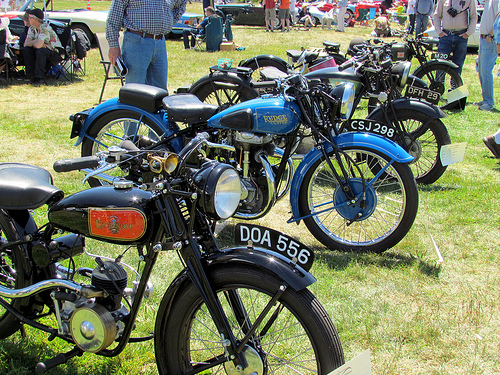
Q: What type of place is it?
A: It is a meadow.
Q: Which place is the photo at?
A: It is at the meadow.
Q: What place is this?
A: It is a meadow.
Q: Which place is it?
A: It is a meadow.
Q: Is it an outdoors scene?
A: Yes, it is outdoors.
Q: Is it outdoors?
A: Yes, it is outdoors.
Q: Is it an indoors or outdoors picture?
A: It is outdoors.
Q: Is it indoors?
A: No, it is outdoors.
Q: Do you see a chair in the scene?
A: Yes, there is a chair.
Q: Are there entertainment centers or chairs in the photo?
A: Yes, there is a chair.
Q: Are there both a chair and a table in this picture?
A: No, there is a chair but no tables.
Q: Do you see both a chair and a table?
A: No, there is a chair but no tables.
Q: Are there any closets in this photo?
A: No, there are no closets.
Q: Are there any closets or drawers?
A: No, there are no closets or drawers.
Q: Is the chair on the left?
A: Yes, the chair is on the left of the image.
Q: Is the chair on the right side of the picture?
A: No, the chair is on the left of the image.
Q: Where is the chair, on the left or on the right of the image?
A: The chair is on the left of the image.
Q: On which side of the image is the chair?
A: The chair is on the left of the image.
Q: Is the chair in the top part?
A: Yes, the chair is in the top of the image.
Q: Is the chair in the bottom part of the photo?
A: No, the chair is in the top of the image.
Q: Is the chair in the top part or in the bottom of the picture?
A: The chair is in the top of the image.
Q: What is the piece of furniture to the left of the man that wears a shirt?
A: The piece of furniture is a chair.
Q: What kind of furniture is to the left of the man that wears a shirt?
A: The piece of furniture is a chair.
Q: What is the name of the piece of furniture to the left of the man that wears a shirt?
A: The piece of furniture is a chair.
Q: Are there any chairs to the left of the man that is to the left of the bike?
A: Yes, there is a chair to the left of the man.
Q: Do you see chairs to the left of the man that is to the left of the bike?
A: Yes, there is a chair to the left of the man.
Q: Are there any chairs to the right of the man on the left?
A: No, the chair is to the left of the man.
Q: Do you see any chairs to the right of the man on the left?
A: No, the chair is to the left of the man.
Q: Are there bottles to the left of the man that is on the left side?
A: No, there is a chair to the left of the man.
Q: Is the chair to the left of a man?
A: Yes, the chair is to the left of a man.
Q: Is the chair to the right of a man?
A: No, the chair is to the left of a man.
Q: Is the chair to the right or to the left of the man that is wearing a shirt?
A: The chair is to the left of the man.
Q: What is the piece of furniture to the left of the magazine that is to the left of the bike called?
A: The piece of furniture is a chair.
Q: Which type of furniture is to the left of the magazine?
A: The piece of furniture is a chair.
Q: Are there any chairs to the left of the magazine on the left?
A: Yes, there is a chair to the left of the magazine.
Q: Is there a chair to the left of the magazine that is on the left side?
A: Yes, there is a chair to the left of the magazine.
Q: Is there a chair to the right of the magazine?
A: No, the chair is to the left of the magazine.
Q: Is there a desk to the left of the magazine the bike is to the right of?
A: No, there is a chair to the left of the magazine.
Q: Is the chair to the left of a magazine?
A: Yes, the chair is to the left of a magazine.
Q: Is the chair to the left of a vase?
A: No, the chair is to the left of a magazine.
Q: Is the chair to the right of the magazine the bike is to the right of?
A: No, the chair is to the left of the magazine.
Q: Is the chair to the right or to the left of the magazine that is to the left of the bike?
A: The chair is to the left of the magazine.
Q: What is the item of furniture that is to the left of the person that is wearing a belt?
A: The piece of furniture is a chair.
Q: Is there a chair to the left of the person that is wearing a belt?
A: Yes, there is a chair to the left of the person.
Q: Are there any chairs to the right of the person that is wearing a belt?
A: No, the chair is to the left of the person.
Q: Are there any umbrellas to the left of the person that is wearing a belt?
A: No, there is a chair to the left of the person.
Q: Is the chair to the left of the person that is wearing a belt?
A: Yes, the chair is to the left of the person.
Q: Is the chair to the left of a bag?
A: No, the chair is to the left of the person.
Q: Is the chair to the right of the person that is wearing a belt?
A: No, the chair is to the left of the person.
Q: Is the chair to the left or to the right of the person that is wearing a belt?
A: The chair is to the left of the person.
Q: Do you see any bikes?
A: Yes, there is a bike.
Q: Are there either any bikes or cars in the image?
A: Yes, there is a bike.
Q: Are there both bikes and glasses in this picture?
A: No, there is a bike but no glasses.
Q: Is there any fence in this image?
A: No, there are no fences.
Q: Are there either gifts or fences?
A: No, there are no fences or gifts.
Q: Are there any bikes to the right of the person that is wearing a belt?
A: Yes, there is a bike to the right of the person.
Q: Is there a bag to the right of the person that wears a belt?
A: No, there is a bike to the right of the person.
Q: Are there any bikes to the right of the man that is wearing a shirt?
A: Yes, there is a bike to the right of the man.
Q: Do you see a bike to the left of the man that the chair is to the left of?
A: No, the bike is to the right of the man.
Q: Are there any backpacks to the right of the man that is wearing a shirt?
A: No, there is a bike to the right of the man.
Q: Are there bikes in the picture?
A: Yes, there is a bike.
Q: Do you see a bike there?
A: Yes, there is a bike.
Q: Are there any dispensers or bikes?
A: Yes, there is a bike.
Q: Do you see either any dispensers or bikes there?
A: Yes, there is a bike.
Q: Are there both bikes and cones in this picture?
A: No, there is a bike but no cones.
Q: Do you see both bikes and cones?
A: No, there is a bike but no cones.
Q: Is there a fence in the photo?
A: No, there are no fences.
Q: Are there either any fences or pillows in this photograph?
A: No, there are no fences or pillows.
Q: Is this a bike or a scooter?
A: This is a bike.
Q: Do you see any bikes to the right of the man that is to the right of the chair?
A: Yes, there is a bike to the right of the man.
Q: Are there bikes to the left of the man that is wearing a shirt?
A: No, the bike is to the right of the man.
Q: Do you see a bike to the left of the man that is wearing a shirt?
A: No, the bike is to the right of the man.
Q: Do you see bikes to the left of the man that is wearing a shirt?
A: No, the bike is to the right of the man.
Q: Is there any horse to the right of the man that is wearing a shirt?
A: No, there is a bike to the right of the man.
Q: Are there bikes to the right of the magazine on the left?
A: Yes, there is a bike to the right of the magazine.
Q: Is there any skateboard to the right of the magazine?
A: No, there is a bike to the right of the magazine.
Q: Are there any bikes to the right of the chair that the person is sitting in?
A: Yes, there is a bike to the right of the chair.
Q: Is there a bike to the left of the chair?
A: No, the bike is to the right of the chair.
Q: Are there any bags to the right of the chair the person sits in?
A: No, there is a bike to the right of the chair.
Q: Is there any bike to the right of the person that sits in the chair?
A: Yes, there is a bike to the right of the person.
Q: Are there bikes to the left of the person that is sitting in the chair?
A: No, the bike is to the right of the person.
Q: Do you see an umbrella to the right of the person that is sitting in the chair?
A: No, there is a bike to the right of the person.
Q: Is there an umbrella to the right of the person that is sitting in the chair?
A: No, there is a bike to the right of the person.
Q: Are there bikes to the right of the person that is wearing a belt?
A: Yes, there is a bike to the right of the person.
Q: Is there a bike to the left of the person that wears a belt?
A: No, the bike is to the right of the person.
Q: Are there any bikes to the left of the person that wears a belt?
A: No, the bike is to the right of the person.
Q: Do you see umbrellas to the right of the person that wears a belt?
A: No, there is a bike to the right of the person.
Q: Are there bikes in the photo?
A: Yes, there is a bike.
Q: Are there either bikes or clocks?
A: Yes, there is a bike.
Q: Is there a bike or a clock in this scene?
A: Yes, there is a bike.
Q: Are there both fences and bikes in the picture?
A: No, there is a bike but no fences.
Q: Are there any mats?
A: No, there are no mats.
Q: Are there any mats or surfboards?
A: No, there are no mats or surfboards.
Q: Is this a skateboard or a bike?
A: This is a bike.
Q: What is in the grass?
A: The bike is in the grass.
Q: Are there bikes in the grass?
A: Yes, there is a bike in the grass.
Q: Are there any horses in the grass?
A: No, there is a bike in the grass.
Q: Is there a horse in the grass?
A: No, there is a bike in the grass.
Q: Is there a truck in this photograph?
A: No, there are no trucks.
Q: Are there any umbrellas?
A: No, there are no umbrellas.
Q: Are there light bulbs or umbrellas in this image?
A: No, there are no umbrellas or light bulbs.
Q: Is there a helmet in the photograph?
A: No, there are no helmets.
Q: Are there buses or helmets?
A: No, there are no helmets or buses.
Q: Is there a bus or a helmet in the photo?
A: No, there are no helmets or buses.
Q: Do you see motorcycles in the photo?
A: Yes, there is a motorcycle.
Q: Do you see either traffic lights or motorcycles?
A: Yes, there is a motorcycle.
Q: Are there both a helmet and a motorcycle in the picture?
A: No, there is a motorcycle but no helmets.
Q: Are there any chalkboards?
A: No, there are no chalkboards.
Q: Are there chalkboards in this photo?
A: No, there are no chalkboards.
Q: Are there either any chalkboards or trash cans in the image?
A: No, there are no chalkboards or trash cans.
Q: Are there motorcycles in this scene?
A: Yes, there is a motorcycle.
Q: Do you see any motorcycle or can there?
A: Yes, there is a motorcycle.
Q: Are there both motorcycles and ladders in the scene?
A: No, there is a motorcycle but no ladders.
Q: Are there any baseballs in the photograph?
A: No, there are no baseballs.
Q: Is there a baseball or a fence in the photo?
A: No, there are no baseballs or fences.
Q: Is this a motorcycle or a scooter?
A: This is a motorcycle.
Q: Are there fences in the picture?
A: No, there are no fences.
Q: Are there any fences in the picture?
A: No, there are no fences.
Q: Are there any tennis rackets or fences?
A: No, there are no fences or tennis rackets.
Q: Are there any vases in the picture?
A: No, there are no vases.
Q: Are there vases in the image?
A: No, there are no vases.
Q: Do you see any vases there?
A: No, there are no vases.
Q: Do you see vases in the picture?
A: No, there are no vases.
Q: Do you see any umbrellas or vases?
A: No, there are no vases or umbrellas.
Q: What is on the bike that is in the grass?
A: The seat is on the bike.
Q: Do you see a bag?
A: No, there are no bags.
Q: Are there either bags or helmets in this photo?
A: No, there are no bags or helmets.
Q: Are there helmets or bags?
A: No, there are no bags or helmets.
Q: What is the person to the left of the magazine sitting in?
A: The person is sitting in the chair.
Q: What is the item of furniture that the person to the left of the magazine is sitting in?
A: The piece of furniture is a chair.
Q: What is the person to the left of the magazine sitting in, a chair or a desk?
A: The person is sitting in a chair.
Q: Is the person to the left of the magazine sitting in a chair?
A: Yes, the person is sitting in a chair.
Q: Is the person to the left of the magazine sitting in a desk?
A: No, the person is sitting in a chair.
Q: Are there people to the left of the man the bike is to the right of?
A: Yes, there is a person to the left of the man.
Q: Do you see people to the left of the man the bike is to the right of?
A: Yes, there is a person to the left of the man.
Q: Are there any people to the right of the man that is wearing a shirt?
A: No, the person is to the left of the man.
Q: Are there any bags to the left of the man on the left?
A: No, there is a person to the left of the man.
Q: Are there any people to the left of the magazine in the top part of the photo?
A: Yes, there is a person to the left of the magazine.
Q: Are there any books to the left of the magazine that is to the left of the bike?
A: No, there is a person to the left of the magazine.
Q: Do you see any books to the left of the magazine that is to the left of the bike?
A: No, there is a person to the left of the magazine.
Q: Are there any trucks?
A: No, there are no trucks.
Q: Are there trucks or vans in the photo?
A: No, there are no trucks or vans.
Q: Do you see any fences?
A: No, there are no fences.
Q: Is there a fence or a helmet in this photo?
A: No, there are no fences or helmets.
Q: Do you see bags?
A: No, there are no bags.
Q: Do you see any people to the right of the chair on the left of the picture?
A: Yes, there is a person to the right of the chair.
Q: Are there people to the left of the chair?
A: No, the person is to the right of the chair.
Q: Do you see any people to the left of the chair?
A: No, the person is to the right of the chair.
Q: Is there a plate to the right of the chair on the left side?
A: No, there is a person to the right of the chair.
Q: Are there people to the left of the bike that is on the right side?
A: Yes, there is a person to the left of the bike.